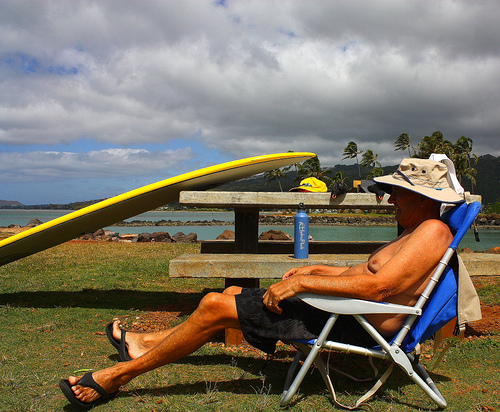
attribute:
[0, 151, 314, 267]
surfboard — yellow, long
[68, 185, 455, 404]
man — without shirt, smiling, not wearing shirt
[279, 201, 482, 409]
lawn chair — blue, gray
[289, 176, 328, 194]
baseball cap — yellow, blue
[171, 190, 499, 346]
picnic table — cement, gray, stone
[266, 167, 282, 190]
palm tree — being blown by wind, blowing in wind, green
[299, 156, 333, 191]
palm tree — being blown by wind, blowing in wind, green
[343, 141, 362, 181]
palm tree — blowing in wind, green, being blown by wind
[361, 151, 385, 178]
palm tree — blowing in wind, green, being blown by wind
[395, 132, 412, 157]
palm tree — blowing in wind, green, being blown by wind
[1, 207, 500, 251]
river — in background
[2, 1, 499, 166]
clouds — dark, gray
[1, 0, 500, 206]
sky — cloudy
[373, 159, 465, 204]
hat — beige, to keep out uv rays, tan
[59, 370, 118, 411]
flip flop — black, for protection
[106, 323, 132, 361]
flip flop — black, for protection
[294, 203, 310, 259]
water bottle — blue, white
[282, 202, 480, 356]
lining — blue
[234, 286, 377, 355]
shorts — for summer weather, cotton, black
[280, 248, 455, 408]
metal — for support, gray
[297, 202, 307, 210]
cap — black